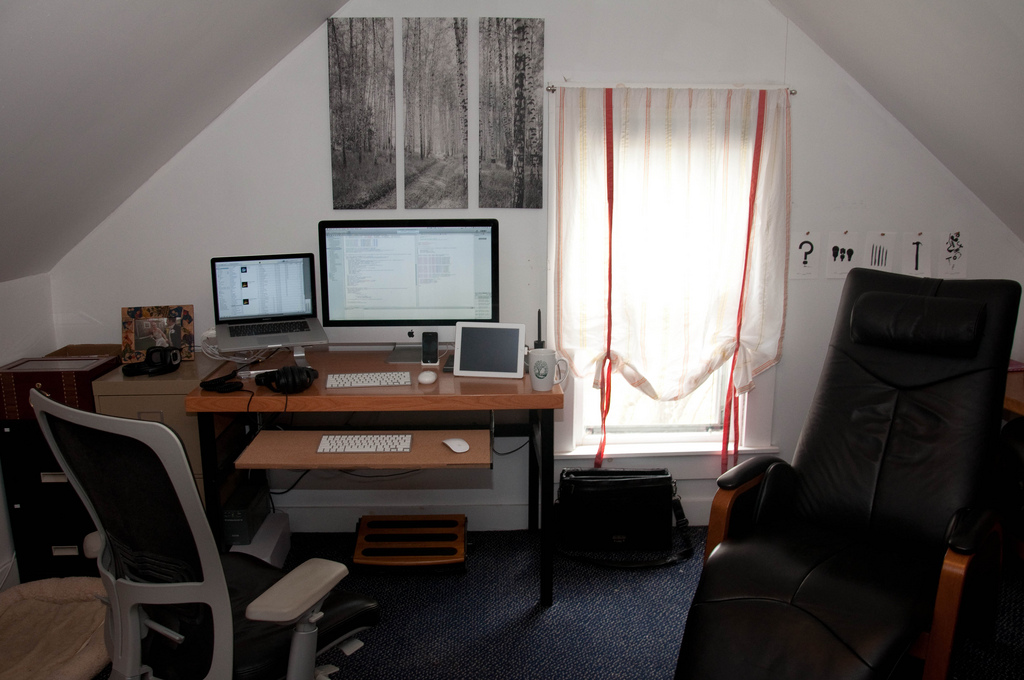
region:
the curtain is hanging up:
[538, 81, 794, 475]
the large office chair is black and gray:
[29, 385, 387, 677]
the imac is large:
[315, 214, 500, 364]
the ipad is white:
[452, 318, 530, 379]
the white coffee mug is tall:
[526, 344, 566, 390]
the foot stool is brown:
[349, 508, 467, 563]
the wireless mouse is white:
[441, 433, 470, 454]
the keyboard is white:
[315, 427, 413, 456]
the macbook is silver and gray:
[210, 250, 331, 355]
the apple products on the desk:
[181, 217, 564, 617]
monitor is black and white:
[321, 221, 500, 326]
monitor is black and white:
[203, 250, 314, 321]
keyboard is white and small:
[314, 428, 413, 448]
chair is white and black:
[32, 386, 365, 678]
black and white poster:
[402, 17, 464, 199]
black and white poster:
[484, 16, 545, 204]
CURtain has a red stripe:
[599, 90, 613, 436]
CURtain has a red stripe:
[719, 89, 768, 429]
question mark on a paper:
[793, 229, 825, 271]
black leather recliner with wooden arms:
[664, 262, 1022, 675]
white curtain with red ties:
[542, 76, 793, 485]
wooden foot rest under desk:
[349, 506, 479, 577]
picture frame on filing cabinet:
[112, 300, 198, 370]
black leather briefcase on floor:
[548, 461, 697, 576]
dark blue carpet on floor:
[282, 531, 715, 674]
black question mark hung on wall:
[788, 225, 820, 280]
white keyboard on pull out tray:
[314, 429, 416, 456]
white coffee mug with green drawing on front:
[522, 345, 570, 393]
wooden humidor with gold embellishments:
[2, 351, 120, 425]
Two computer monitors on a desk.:
[198, 211, 519, 358]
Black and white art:
[316, 13, 554, 217]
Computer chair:
[25, 380, 381, 669]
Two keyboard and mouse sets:
[316, 370, 473, 462]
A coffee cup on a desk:
[525, 344, 567, 396]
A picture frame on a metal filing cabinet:
[111, 309, 200, 368]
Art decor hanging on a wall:
[795, 220, 972, 281]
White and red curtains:
[552, 85, 796, 484]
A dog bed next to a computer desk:
[3, 568, 149, 677]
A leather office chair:
[666, 250, 1015, 666]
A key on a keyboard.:
[357, 437, 365, 447]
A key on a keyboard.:
[367, 438, 377, 446]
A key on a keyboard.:
[381, 433, 392, 440]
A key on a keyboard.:
[332, 438, 337, 446]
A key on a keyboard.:
[331, 374, 342, 382]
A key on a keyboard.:
[354, 373, 364, 380]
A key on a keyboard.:
[381, 371, 391, 381]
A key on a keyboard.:
[395, 373, 402, 381]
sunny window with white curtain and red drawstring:
[540, 80, 801, 461]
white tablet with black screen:
[447, 318, 530, 389]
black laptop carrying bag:
[544, 463, 703, 581]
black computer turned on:
[308, 214, 511, 364]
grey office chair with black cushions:
[22, 378, 378, 676]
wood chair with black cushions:
[680, 255, 1019, 676]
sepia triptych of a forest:
[314, 11, 550, 217]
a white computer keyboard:
[311, 429, 423, 459]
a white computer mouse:
[433, 429, 479, 465]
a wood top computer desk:
[187, 344, 570, 627]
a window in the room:
[564, 96, 760, 447]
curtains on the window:
[554, 86, 773, 463]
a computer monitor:
[321, 219, 481, 318]